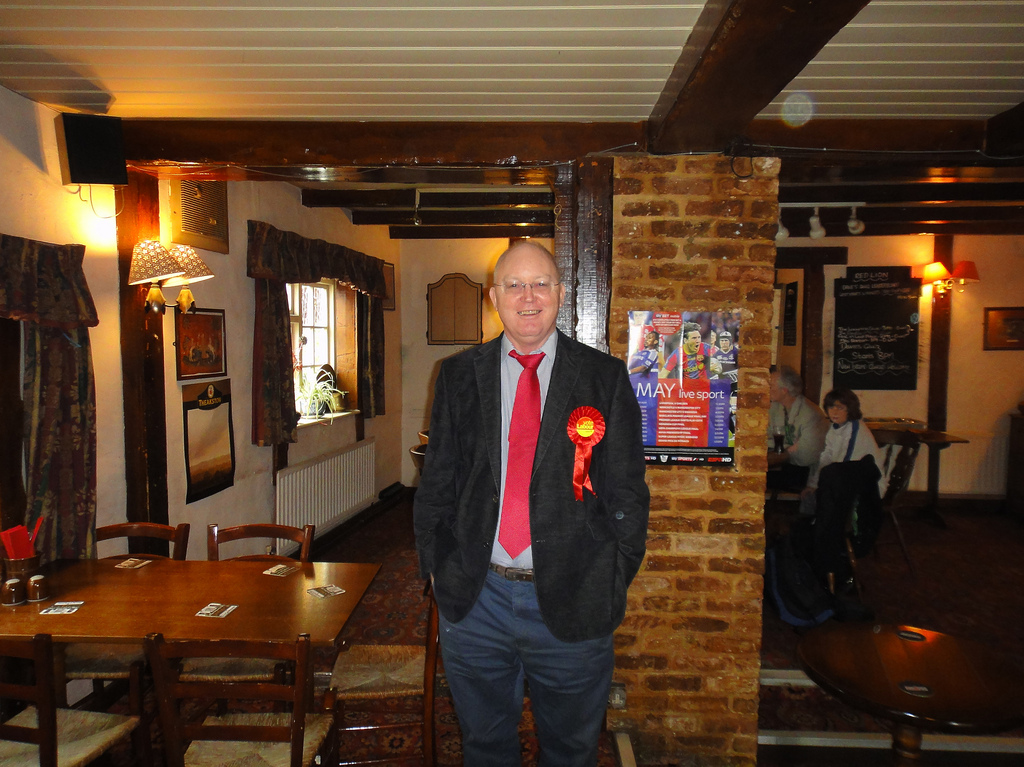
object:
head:
[488, 240, 567, 346]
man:
[413, 241, 652, 767]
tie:
[496, 350, 546, 560]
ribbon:
[566, 404, 607, 501]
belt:
[488, 561, 534, 583]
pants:
[436, 559, 616, 766]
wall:
[610, 153, 783, 765]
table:
[0, 559, 380, 766]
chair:
[325, 584, 445, 767]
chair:
[142, 629, 337, 766]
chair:
[0, 630, 143, 767]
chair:
[203, 520, 316, 715]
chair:
[83, 519, 192, 717]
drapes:
[246, 219, 388, 448]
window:
[282, 279, 338, 419]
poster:
[629, 308, 741, 466]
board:
[833, 278, 921, 391]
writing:
[837, 325, 917, 377]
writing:
[837, 273, 920, 303]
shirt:
[807, 419, 890, 499]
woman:
[778, 386, 891, 559]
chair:
[829, 437, 922, 563]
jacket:
[411, 325, 650, 645]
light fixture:
[848, 207, 867, 237]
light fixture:
[808, 207, 827, 241]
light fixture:
[774, 207, 790, 242]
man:
[766, 365, 831, 528]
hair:
[777, 363, 805, 397]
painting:
[173, 304, 227, 381]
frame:
[173, 306, 227, 382]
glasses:
[493, 277, 564, 296]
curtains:
[2, 231, 100, 570]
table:
[789, 614, 1024, 767]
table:
[906, 427, 971, 530]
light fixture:
[126, 238, 187, 315]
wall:
[0, 94, 397, 714]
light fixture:
[162, 244, 216, 315]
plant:
[295, 369, 349, 427]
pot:
[299, 400, 326, 417]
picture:
[180, 376, 238, 505]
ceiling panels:
[0, 0, 707, 123]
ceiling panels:
[747, 0, 1024, 124]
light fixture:
[922, 260, 954, 294]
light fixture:
[950, 261, 982, 293]